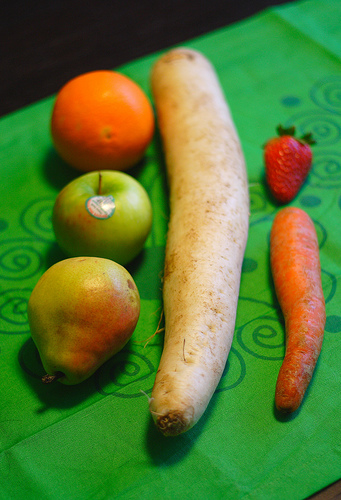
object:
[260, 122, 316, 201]
strawberry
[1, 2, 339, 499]
cloth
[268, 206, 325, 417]
carrot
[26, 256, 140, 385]
pear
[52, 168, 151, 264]
apple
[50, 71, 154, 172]
orange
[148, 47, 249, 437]
parsnip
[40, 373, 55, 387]
stem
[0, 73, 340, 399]
design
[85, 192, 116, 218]
label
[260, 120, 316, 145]
stem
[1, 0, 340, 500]
table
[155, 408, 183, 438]
roots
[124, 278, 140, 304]
bruise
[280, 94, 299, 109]
dot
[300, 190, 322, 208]
dot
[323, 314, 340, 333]
dot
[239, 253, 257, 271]
dot